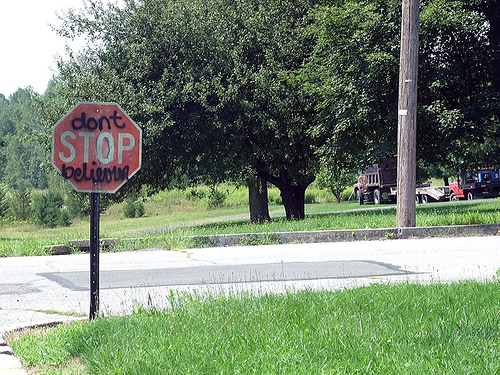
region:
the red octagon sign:
[51, 102, 141, 193]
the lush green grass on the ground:
[152, 303, 417, 373]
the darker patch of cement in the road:
[38, 252, 412, 287]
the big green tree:
[59, 5, 499, 220]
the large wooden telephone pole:
[395, 0, 418, 229]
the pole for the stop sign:
[87, 192, 102, 319]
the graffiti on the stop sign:
[67, 112, 126, 184]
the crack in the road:
[170, 245, 220, 267]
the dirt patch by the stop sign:
[5, 319, 61, 339]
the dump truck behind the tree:
[348, 162, 397, 205]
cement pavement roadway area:
[102, 233, 419, 280]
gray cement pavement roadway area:
[110, 246, 445, 278]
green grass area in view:
[110, 265, 467, 361]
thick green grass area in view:
[107, 260, 482, 365]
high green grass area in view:
[107, 255, 472, 365]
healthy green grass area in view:
[111, 276, 478, 362]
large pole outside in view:
[392, 0, 422, 232]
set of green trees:
[132, 16, 373, 216]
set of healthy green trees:
[136, 3, 362, 210]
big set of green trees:
[146, 11, 378, 206]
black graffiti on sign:
[36, 99, 166, 219]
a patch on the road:
[27, 225, 418, 290]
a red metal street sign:
[36, 96, 168, 209]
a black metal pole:
[76, 190, 118, 325]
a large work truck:
[330, 146, 428, 210]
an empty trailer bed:
[393, 175, 467, 216]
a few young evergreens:
[8, 174, 155, 224]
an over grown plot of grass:
[51, 269, 476, 374]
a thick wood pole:
[380, 7, 445, 243]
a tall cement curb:
[116, 221, 471, 251]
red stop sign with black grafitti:
[9, 72, 229, 347]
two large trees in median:
[86, 7, 383, 246]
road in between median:
[16, 211, 494, 319]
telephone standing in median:
[386, 3, 453, 284]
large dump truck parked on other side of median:
[356, 151, 420, 217]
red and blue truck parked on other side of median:
[446, 166, 499, 210]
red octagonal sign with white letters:
[43, 76, 135, 221]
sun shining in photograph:
[12, 10, 462, 298]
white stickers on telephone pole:
[386, 74, 421, 138]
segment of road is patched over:
[24, 260, 466, 290]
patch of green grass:
[140, 307, 434, 364]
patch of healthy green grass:
[126, 298, 466, 361]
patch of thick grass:
[98, 260, 468, 360]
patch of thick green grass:
[98, 271, 465, 362]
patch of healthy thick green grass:
[86, 271, 488, 364]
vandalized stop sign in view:
[34, 90, 166, 216]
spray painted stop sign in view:
[32, 86, 172, 245]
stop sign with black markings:
[42, 83, 165, 236]